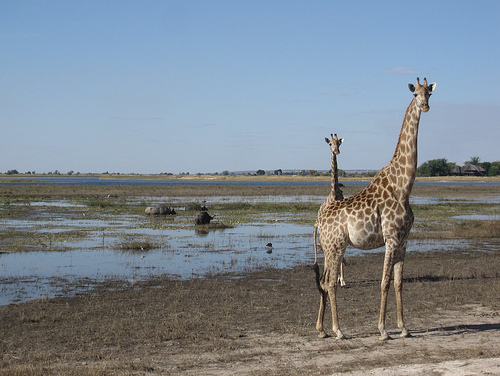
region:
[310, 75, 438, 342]
two giraffes near each other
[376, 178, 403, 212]
brown spots on giraffe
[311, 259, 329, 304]
dark hair on end of giraffe's tail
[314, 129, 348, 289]
baby giraffe standing behind adult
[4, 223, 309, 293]
muddy swamp water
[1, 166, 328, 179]
trees in the distance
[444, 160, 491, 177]
structure in the distance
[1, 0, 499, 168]
clear light blue sky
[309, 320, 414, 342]
giraffe's feet in the sand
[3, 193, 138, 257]
weeds growing in swamp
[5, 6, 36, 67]
white clouds in blue sky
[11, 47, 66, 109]
white clouds in blue sky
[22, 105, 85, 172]
white clouds in blue sky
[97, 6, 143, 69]
white clouds in blue sky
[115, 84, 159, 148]
white clouds in blue sky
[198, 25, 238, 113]
white clouds in blue sky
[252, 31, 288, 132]
white clouds in blue sky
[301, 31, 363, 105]
white clouds in blue sky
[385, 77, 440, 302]
spotted giraffe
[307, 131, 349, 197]
giraffe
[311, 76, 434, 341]
two standing giraffes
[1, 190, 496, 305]
a grassy marsh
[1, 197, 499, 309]
grass growing in the water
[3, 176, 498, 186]
blue water in the backgound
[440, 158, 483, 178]
a house in the background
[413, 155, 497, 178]
trees growing around the house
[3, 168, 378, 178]
a line of trees beside the water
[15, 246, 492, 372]
dead gray colored grass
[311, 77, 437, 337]
brown and tan giraffe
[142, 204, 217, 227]
two large animals in the water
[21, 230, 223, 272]
The water in the land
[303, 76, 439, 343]
The giraffes are looking forward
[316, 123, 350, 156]
The head of the giraffe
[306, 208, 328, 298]
The tail of the giraffe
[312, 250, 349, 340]
The back legs of the giraffe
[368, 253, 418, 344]
The front legs of the giraffe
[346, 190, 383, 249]
The stomach of the giraffe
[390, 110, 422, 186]
The neck of the giraffe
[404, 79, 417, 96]
The ear of the giraffe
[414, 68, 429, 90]
The horns of the giraffe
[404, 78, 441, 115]
The head of an adult giraffe standing on dead grass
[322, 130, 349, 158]
The head of a young giraffe standing on dead grass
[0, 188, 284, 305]
Swamp like water pool in africa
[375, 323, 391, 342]
Front hoof of an adult giraffe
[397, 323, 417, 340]
Front hoof of an adult giraffe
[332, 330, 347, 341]
Rear hoof of an adult giraffe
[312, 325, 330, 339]
Rear hoof on an adult giraffe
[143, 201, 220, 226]
Animals in the background in pool of swamp water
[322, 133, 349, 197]
Young giraffe behind of an adult one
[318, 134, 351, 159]
The head of a young giraffe